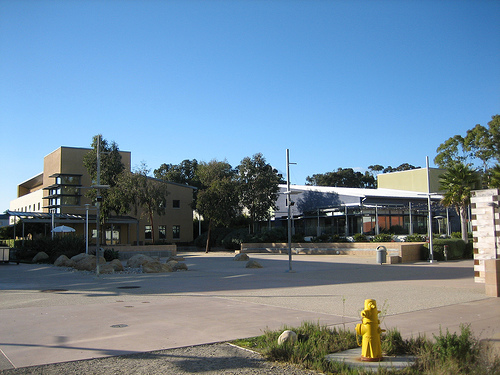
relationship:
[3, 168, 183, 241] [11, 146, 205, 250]
windows on building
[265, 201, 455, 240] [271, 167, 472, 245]
windows on building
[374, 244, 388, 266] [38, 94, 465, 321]
garbage can in front of building.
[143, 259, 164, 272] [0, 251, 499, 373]
keyrock on lot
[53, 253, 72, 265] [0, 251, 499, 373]
keyrock on lot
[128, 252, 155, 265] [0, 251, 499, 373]
keyrock on lot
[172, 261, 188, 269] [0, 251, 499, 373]
keyrock on lot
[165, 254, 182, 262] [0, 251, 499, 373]
keyrock on lot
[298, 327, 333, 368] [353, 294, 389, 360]
grass by fire hydrant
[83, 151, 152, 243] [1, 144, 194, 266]
tree by building